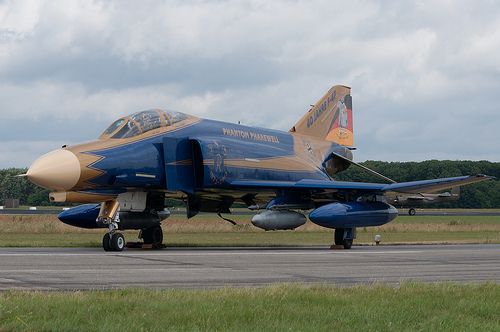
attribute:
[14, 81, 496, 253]
fighter jet — blue, gold, yellow, large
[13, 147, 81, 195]
nose — white, tan, pointy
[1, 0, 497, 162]
clouds — white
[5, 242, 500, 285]
runway — clean, black, gray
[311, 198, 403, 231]
engine — blue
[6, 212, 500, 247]
grass — brown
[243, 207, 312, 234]
rocket — small, gray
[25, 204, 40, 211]
post — white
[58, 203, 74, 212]
post — white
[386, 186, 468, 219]
military plane — red, yellow